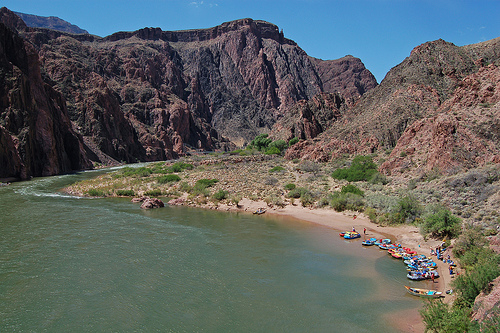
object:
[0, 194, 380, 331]
water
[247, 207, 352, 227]
sand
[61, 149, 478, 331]
beach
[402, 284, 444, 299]
boat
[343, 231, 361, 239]
boat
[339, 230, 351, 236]
boat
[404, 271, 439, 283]
boat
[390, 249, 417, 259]
boat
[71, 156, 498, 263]
ground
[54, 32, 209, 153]
rocks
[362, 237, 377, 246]
boats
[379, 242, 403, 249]
boats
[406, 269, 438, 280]
boats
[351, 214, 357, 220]
person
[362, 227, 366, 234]
person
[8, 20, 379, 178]
cliff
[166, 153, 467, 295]
shore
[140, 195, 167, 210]
rock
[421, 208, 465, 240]
bush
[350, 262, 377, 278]
sand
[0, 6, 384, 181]
mountains